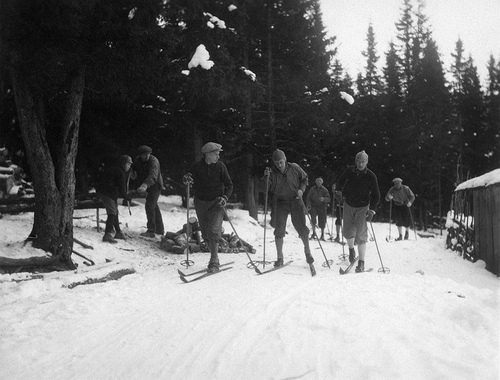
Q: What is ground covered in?
A: Snow.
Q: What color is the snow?
A: White.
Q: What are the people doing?
A: Skiing.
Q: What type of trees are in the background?
A: Pine trees.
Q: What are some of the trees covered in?
A: Snow.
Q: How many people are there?
A: Eight.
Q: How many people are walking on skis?
A: Six.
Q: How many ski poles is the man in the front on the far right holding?
A: Two.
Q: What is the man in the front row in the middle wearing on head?
A: Beanie.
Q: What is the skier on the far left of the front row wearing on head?
A: A newsboy hat.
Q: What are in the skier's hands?
A: Ski poles.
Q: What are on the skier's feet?
A: Skis.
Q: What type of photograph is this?
A: Black and white.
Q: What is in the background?
A: A grouping of trees.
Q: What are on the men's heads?
A: Hats.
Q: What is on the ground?
A: Snow.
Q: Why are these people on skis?
A: Cross country skiing.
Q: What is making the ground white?
A: Snow.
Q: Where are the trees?
A: Background.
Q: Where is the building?
A: Right side of the frame.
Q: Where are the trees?
A: Behind the skiers.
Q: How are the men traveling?
A: On skis.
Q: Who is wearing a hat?
A: The men.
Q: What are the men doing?
A: Skiing.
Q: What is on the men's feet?
A: Skis.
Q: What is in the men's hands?
A: Ski poles.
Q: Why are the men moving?
A: They are skiing.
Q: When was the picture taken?
A: Daytime.